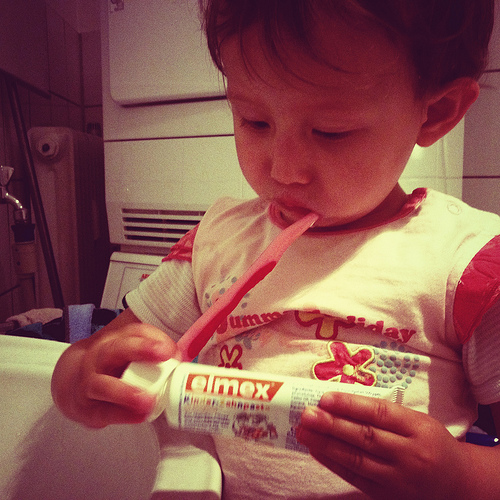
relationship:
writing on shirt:
[217, 305, 418, 345] [125, 196, 499, 497]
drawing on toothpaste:
[232, 413, 277, 444] [119, 356, 404, 457]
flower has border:
[294, 308, 354, 341] [292, 311, 356, 338]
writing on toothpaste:
[181, 373, 274, 399] [119, 356, 404, 457]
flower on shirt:
[314, 341, 377, 388] [125, 196, 499, 497]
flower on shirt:
[219, 346, 244, 369] [125, 196, 499, 497]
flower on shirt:
[294, 308, 354, 341] [125, 196, 499, 497]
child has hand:
[51, 1, 500, 498] [73, 324, 174, 429]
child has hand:
[51, 1, 500, 498] [296, 393, 464, 495]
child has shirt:
[51, 1, 500, 498] [125, 196, 499, 497]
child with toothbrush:
[51, 1, 500, 498] [175, 212, 320, 365]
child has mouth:
[51, 1, 500, 498] [268, 194, 321, 223]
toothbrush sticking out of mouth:
[175, 212, 320, 365] [268, 194, 321, 223]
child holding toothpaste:
[51, 1, 500, 498] [119, 356, 404, 457]